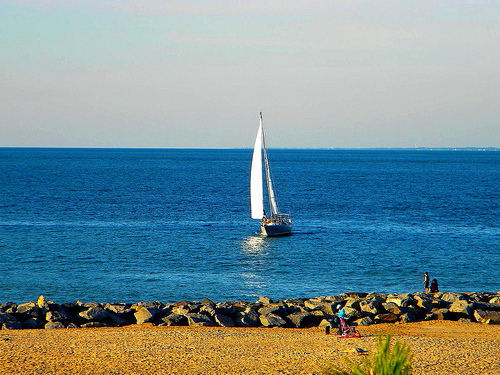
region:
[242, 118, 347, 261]
a sailboat on the water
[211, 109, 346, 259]
a sailboat with a white sail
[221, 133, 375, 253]
a sailboat on the ocean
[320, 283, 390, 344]
a person by the water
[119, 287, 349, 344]
rocks near the water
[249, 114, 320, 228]
a tall white sail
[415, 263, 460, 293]
a person standing on rocks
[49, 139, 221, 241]
lots of blue ocean water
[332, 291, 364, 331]
a person with a blue shirt on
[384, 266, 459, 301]
people standing on big rocks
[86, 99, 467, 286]
the water is blue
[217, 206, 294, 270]
the water is reflecting the sail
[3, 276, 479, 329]
rocks along the water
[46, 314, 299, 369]
the sand is tan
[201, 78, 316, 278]
sailboat in the water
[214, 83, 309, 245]
the sail is white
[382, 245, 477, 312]
people are by the water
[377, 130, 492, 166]
houses and land in the distance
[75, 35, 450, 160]
the sky is overcast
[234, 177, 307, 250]
people are on the boat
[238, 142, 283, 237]
White sail on boat.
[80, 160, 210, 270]
Water is bright blue.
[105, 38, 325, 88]
Sky is grayish blue.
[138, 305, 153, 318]
Large gray rock on shore.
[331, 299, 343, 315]
Person wearing hat on head.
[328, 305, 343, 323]
Person wearing blue shirt.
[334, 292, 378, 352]
Person standing on beach.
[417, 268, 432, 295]
Person standing on rocks.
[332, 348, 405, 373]
Green plant near beach.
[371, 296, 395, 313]
Large gray rock on shore.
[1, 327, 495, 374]
Amber colored sand on beach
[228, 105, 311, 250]
Sailboat sailing through blue ocean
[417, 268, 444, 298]
People standing on rocky beach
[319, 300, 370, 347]
Person in turquoise shirt on beach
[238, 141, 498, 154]
Distant shoreline on other side of ocean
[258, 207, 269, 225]
Person standing on deck of sailboat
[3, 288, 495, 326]
Large brown rocks on shoreline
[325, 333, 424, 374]
Single green bush on beach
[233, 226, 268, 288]
Reflection of boat's sail on water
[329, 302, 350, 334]
Beachgoer wearing a white hat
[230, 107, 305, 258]
A sailboat on blue water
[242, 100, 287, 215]
A large white sail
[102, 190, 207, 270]
Blue water with ripples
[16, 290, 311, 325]
An wall of rocks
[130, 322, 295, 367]
Gravel or sand near water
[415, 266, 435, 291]
A person standing on rocks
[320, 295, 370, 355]
A person standing in front of rock wall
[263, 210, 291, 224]
People on board the sailboat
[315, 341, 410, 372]
A plant of green grass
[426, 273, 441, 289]
A person sitting on rocks